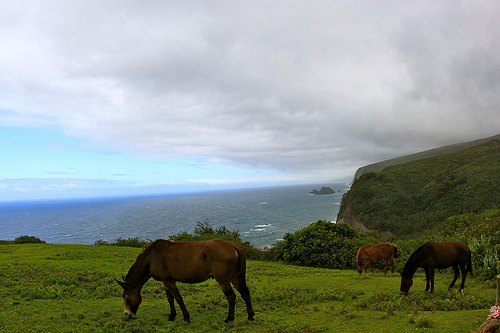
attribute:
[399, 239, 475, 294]
horse — brown, grazing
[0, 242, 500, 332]
grass — green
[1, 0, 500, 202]
sky — dark, overcast, stormy, blue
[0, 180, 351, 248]
water — blue, choppy, large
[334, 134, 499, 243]
cliff — steep, green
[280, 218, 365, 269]
bush — lush, green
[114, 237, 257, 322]
horse — brown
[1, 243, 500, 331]
field — grassy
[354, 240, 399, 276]
horse — little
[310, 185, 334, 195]
boulder — small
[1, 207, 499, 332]
hill — small